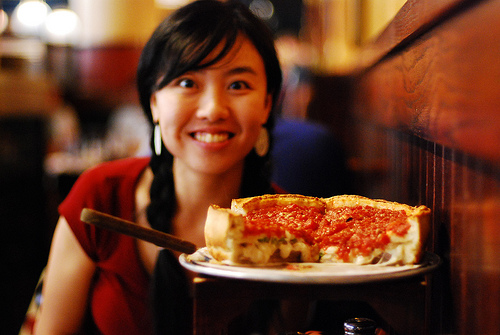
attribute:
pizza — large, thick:
[204, 190, 431, 268]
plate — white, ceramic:
[176, 243, 431, 283]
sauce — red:
[243, 203, 411, 256]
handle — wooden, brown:
[75, 203, 200, 256]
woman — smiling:
[32, 1, 294, 335]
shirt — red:
[57, 152, 298, 333]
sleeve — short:
[55, 156, 108, 262]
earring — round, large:
[150, 121, 165, 161]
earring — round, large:
[254, 121, 272, 157]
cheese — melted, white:
[241, 236, 409, 269]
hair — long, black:
[131, 5, 284, 334]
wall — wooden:
[334, 4, 497, 332]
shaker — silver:
[338, 313, 378, 334]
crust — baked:
[200, 200, 243, 266]